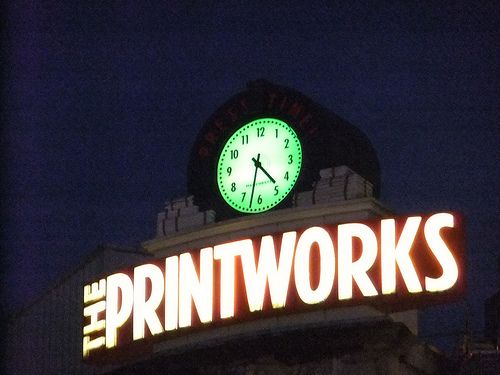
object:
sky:
[0, 0, 499, 353]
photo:
[0, 0, 500, 375]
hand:
[249, 153, 276, 207]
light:
[83, 118, 459, 357]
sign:
[82, 211, 457, 357]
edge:
[186, 77, 380, 223]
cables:
[0, 242, 154, 375]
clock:
[216, 117, 304, 214]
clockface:
[217, 117, 304, 214]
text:
[82, 211, 466, 362]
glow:
[81, 211, 459, 358]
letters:
[81, 180, 460, 358]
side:
[0, 241, 154, 375]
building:
[0, 78, 500, 375]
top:
[139, 78, 398, 263]